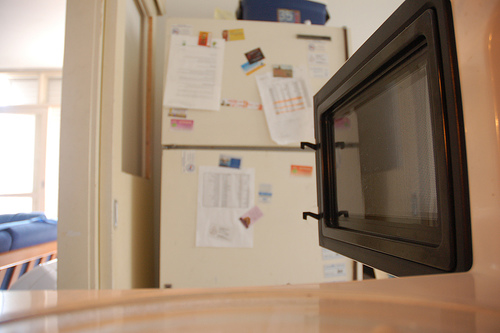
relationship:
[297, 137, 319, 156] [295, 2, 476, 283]
hook locks door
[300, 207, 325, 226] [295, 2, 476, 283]
hook locks door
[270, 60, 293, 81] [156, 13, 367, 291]
magnets on fridge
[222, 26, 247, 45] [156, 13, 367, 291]
magnets on fridge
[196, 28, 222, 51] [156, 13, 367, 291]
magnets on fridge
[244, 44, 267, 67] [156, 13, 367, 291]
magnets on fridge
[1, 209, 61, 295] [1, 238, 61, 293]
couch has frame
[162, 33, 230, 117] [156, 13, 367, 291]
paper attached to fridge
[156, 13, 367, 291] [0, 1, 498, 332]
fridge in kitchen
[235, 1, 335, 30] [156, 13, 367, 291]
tub on fridge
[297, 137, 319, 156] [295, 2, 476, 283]
hook on door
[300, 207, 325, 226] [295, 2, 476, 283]
hook on door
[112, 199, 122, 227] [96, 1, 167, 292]
switch on wall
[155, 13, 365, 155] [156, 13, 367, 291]
freezer of fridge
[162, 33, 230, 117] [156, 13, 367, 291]
paper on fridge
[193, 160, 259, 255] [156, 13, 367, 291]
paper on fridge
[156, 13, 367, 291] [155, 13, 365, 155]
fridge has freezer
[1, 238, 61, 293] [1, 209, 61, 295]
frame to couch